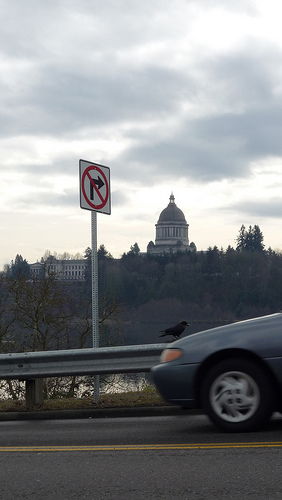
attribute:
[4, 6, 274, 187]
cloud — white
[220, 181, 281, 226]
cloud — white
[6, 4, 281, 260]
sky — blue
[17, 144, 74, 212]
cloud — white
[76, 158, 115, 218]
sign — white, red, black, street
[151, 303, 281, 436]
car — gray, grey, black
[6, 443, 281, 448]
line — yellow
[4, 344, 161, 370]
railing — metal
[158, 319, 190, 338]
bird — black, sitting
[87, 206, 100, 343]
pole — metal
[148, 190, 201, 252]
building — brown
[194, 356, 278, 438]
tire — black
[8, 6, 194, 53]
cloud — white